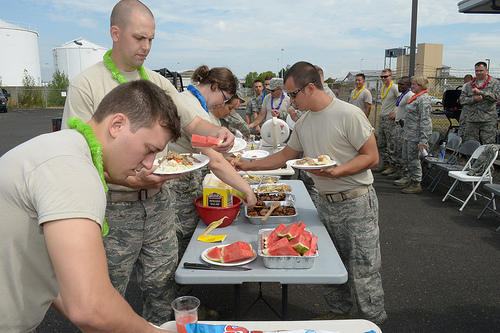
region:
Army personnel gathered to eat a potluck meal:
[2, 1, 495, 328]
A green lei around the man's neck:
[52, 110, 131, 241]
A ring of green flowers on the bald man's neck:
[97, 47, 167, 109]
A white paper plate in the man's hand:
[283, 158, 341, 178]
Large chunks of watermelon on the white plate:
[204, 241, 259, 266]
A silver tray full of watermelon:
[257, 225, 322, 270]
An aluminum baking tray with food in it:
[255, 224, 320, 273]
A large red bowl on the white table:
[194, 191, 244, 228]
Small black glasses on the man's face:
[281, 83, 313, 107]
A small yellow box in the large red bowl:
[198, 184, 231, 207]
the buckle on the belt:
[321, 189, 345, 205]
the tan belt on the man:
[106, 181, 166, 203]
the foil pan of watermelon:
[258, 223, 320, 265]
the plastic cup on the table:
[167, 291, 205, 329]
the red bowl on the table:
[191, 194, 240, 226]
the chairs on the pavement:
[433, 136, 498, 214]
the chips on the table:
[183, 322, 314, 331]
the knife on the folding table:
[178, 258, 253, 275]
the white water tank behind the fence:
[1, 18, 43, 90]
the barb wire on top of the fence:
[413, 63, 477, 76]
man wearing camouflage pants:
[233, 58, 388, 332]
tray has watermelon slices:
[257, 218, 318, 270]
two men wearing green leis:
[3, 0, 230, 328]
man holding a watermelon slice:
[57, 0, 236, 322]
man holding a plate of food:
[243, 59, 382, 323]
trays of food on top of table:
[176, 170, 348, 317]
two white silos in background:
[0, 13, 111, 113]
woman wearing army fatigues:
[395, 75, 435, 198]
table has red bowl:
[193, 183, 240, 228]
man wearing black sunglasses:
[235, 59, 384, 326]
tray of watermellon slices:
[258, 217, 321, 271]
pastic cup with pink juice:
[171, 295, 200, 331]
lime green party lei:
[69, 110, 118, 241]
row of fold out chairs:
[432, 128, 499, 214]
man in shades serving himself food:
[240, 61, 392, 331]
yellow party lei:
[378, 80, 395, 101]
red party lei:
[471, 72, 492, 96]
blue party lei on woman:
[182, 63, 239, 120]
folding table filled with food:
[174, 171, 352, 289]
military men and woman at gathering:
[7, 1, 498, 312]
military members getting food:
[98, 21, 402, 321]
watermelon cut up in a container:
[259, 215, 337, 276]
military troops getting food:
[43, 28, 481, 311]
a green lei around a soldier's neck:
[52, 100, 138, 237]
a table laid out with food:
[246, 135, 301, 287]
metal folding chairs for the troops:
[449, 133, 496, 212]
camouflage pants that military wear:
[338, 193, 410, 320]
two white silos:
[7, 21, 117, 107]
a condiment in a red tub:
[202, 173, 244, 228]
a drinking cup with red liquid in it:
[167, 300, 209, 327]